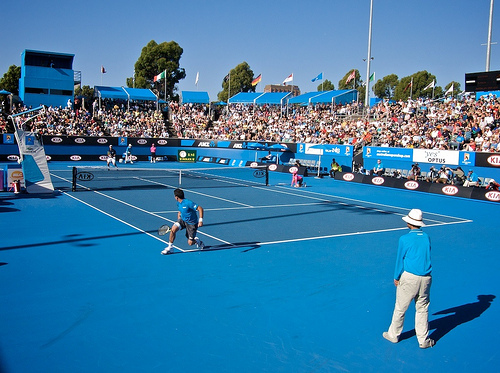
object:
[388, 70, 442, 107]
tree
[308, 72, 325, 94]
flags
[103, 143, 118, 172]
player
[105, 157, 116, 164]
shorts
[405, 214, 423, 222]
band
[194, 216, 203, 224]
armband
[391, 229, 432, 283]
shirt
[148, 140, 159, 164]
person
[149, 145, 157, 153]
shirt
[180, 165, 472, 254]
lines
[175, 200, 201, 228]
shirt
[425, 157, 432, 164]
letter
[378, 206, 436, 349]
man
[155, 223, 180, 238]
racquet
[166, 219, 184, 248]
leg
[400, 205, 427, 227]
hat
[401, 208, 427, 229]
head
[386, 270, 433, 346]
pants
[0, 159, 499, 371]
court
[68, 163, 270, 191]
net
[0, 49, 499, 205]
bleacher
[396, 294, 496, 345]
shadow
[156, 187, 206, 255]
man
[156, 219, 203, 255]
down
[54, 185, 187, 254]
lines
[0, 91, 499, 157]
crowd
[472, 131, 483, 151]
people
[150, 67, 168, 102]
flag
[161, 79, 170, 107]
pole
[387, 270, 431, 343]
pair